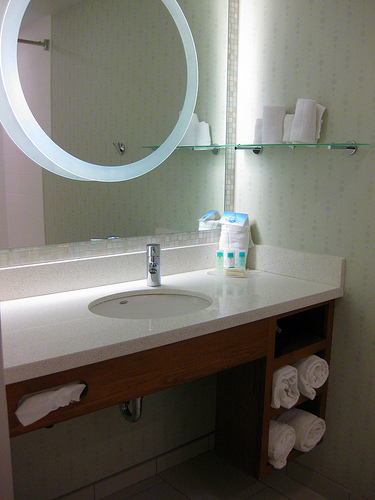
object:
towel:
[271, 366, 302, 414]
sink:
[88, 288, 212, 325]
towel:
[296, 352, 325, 386]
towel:
[269, 421, 296, 473]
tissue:
[14, 379, 90, 429]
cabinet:
[6, 307, 333, 479]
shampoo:
[215, 251, 225, 266]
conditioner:
[225, 249, 237, 267]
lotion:
[235, 250, 249, 269]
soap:
[218, 268, 247, 290]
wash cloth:
[253, 118, 263, 144]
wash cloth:
[281, 112, 296, 141]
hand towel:
[261, 105, 288, 145]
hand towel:
[289, 98, 326, 150]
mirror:
[1, 1, 238, 256]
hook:
[113, 139, 127, 155]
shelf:
[231, 141, 366, 152]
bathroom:
[1, 6, 373, 334]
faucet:
[146, 243, 162, 289]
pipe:
[120, 396, 144, 421]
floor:
[104, 449, 327, 500]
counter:
[0, 245, 344, 429]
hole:
[116, 297, 131, 306]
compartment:
[267, 309, 332, 474]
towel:
[217, 214, 251, 257]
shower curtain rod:
[17, 35, 50, 47]